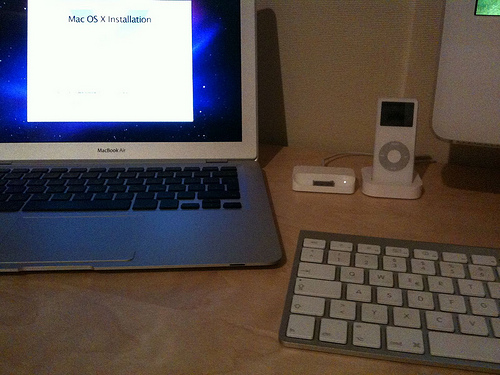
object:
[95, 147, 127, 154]
logo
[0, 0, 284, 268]
laptop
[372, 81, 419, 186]
ipod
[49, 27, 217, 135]
memeo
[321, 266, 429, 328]
key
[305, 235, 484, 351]
keyboard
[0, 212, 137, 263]
mousepad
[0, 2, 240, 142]
screen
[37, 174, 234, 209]
keys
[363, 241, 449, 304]
keys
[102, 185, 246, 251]
surface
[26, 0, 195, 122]
image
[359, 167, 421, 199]
stand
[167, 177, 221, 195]
buttons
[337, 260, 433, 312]
buttons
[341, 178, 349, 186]
light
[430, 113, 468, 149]
corner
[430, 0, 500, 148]
monitor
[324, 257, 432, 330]
letters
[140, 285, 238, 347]
desk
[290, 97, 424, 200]
device